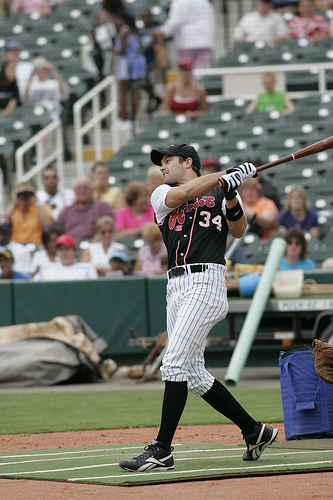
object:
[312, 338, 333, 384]
baseball glove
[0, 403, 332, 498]
dirt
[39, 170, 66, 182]
sunglasses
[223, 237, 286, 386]
gray pipe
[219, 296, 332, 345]
trailer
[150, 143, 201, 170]
cap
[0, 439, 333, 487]
mat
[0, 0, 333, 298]
audience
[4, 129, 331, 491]
game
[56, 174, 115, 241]
older man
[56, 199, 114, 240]
purple shirt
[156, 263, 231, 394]
uniform pants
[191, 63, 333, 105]
railing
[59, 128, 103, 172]
steps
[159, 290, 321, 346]
trailer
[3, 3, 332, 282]
spectators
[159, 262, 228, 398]
pants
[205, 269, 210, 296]
stripe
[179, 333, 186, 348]
stripe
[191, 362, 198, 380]
stripe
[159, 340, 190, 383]
stripe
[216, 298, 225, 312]
stripe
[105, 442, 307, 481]
cleat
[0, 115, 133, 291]
stairs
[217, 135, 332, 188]
baseball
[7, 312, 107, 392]
tarp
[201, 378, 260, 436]
stocking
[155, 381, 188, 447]
stocking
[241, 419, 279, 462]
sneaker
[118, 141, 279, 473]
man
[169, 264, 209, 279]
belt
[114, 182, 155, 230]
person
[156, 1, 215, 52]
jacket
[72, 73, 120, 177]
rail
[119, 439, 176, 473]
shoe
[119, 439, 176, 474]
foot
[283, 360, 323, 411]
handle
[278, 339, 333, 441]
bag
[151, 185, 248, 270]
jersey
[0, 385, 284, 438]
ground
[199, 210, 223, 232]
number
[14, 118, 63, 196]
railing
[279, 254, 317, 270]
shirt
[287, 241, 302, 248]
sunglasses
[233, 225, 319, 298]
woman